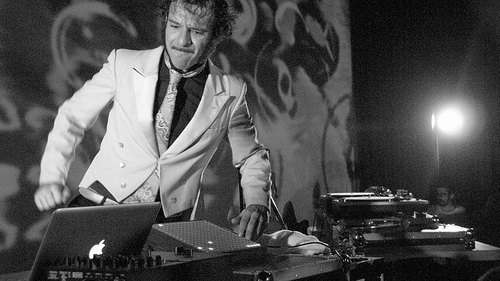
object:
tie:
[155, 50, 209, 157]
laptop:
[27, 202, 162, 281]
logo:
[88, 239, 105, 259]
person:
[426, 186, 465, 223]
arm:
[228, 85, 271, 205]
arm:
[37, 51, 113, 184]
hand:
[231, 205, 267, 239]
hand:
[34, 184, 71, 212]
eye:
[171, 25, 180, 30]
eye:
[193, 30, 203, 35]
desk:
[0, 240, 499, 281]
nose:
[175, 28, 192, 47]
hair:
[156, 0, 243, 41]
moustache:
[171, 46, 195, 54]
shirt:
[154, 51, 211, 147]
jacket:
[39, 45, 273, 219]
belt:
[78, 188, 119, 206]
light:
[436, 108, 464, 133]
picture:
[3, 3, 499, 277]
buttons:
[118, 142, 124, 148]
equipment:
[42, 246, 236, 281]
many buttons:
[45, 254, 171, 267]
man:
[34, 0, 271, 240]